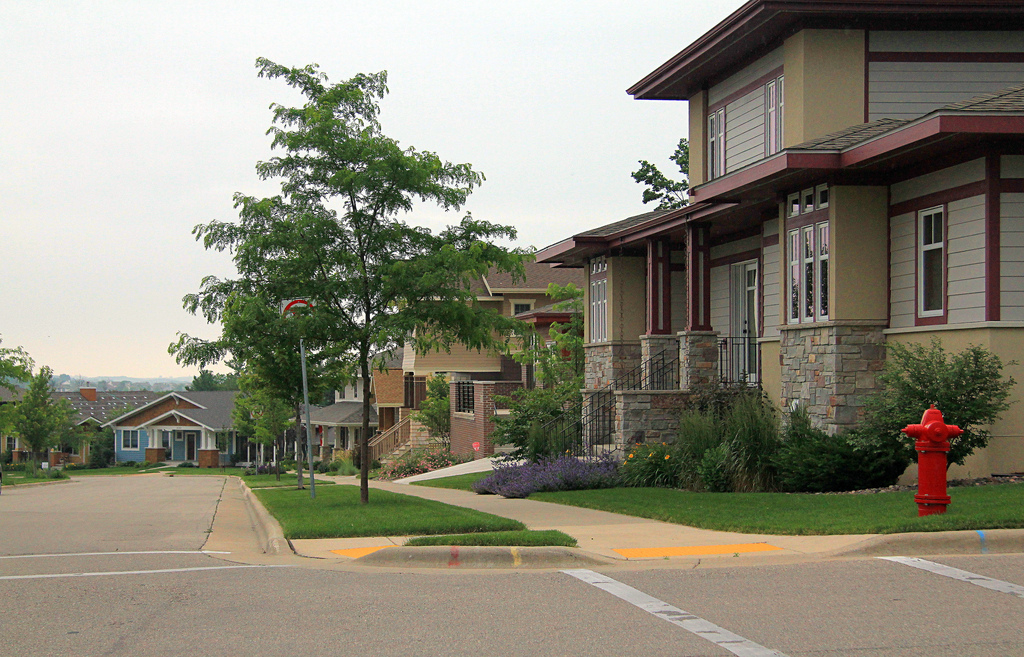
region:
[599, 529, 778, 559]
white painted strip on ground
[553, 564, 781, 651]
white line in the street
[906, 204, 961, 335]
window on the house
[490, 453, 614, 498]
purple flowers in yard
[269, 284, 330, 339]
covered up traffic sign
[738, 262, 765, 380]
front door to the house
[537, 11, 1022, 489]
brown and burgundy house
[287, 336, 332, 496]
pole from the sign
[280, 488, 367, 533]
green grass on the ground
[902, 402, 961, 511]
red fire hydrant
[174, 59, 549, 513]
large tree with a thin trunk and green leaves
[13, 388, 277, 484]
blue, brown, and white house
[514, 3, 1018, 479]
house with many abstract shaped windows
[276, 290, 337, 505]
street sign hidden in distance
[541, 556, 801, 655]
white eroded line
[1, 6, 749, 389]
Overcast cloudy grey sky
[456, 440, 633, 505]
purple flowers growing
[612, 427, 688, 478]
assortment of yellow flowers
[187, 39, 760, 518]
a tree on front a home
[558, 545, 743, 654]
white line on the street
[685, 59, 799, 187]
a window on a second floor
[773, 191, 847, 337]
a window of a home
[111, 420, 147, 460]
a window of a home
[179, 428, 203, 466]
the door of a house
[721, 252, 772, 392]
the door of a house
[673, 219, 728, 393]
the column of a house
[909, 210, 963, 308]
a window on a building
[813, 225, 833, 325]
a window on a building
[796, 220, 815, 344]
a window on a building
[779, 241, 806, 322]
a window on a building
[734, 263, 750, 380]
a window on a building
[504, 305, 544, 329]
a window on a building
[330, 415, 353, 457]
a window on a building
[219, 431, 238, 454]
a window on a building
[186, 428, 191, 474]
a window on a building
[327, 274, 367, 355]
green leaves on the tree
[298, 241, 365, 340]
green leaves on the tree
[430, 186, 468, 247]
green leaves on the tree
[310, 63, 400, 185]
green leaves on the tree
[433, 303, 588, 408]
green leaves on the tree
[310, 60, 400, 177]
green leaves on the tree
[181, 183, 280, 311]
green leaves on the tree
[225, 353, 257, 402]
green leaves on the tree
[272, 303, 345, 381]
green leaves on the tree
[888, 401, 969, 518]
Fire hydrant near street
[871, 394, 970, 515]
Hydrant near the road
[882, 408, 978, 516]
Hydrant near the street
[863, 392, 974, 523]
Red hydrant near road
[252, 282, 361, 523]
Sign on a pole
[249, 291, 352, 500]
Street sign on pole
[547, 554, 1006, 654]
Crosswalk on the street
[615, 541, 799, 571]
A yellow stripe on the sidewalk.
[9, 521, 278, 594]
White lines in the road.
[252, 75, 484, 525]
A green tree in front of the house.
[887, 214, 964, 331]
A window on the house.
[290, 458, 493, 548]
The grass is trimmed and green.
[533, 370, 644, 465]
Railings on the steps of stairs.